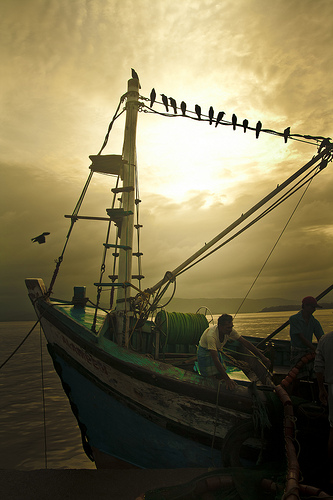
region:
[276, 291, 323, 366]
Man wearing red hat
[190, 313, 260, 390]
Man wearing white shirt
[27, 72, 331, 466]
Large dirty boat in ocean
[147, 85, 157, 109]
Bird sitting on rope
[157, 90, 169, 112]
Bird sitting on rope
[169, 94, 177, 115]
Bird sitting on rope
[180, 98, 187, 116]
Bird sitting on rope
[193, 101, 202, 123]
Bird sitting on rope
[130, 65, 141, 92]
Bird sitting on top of wooden post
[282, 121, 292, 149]
Bird sitting on rope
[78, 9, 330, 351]
Sunset over a fishing boat.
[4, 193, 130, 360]
Bird landing on the deck of a boat.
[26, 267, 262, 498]
An old boat in need of a paint job.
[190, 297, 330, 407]
Fisherman working on a boat.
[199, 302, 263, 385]
A man in a white shirt.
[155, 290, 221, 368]
Green rope on a spool.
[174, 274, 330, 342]
The cost line of a boats home port.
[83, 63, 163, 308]
the mast of a boat.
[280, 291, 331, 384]
A man looking out to see.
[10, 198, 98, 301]
A bird flying through the sky.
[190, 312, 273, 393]
man in white t shirt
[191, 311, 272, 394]
man with dark hair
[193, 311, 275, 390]
man with something green wrapped around his waist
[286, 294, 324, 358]
man in red hat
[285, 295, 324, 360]
man in blue shirt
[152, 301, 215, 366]
spool of rope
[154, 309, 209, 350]
green rope on the spool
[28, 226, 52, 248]
bird flying in the air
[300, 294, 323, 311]
mans red cap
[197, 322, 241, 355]
mans white shirt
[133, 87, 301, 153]
black birds on power line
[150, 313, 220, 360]
green spooled rope on boat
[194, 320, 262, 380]
man wearing white shirt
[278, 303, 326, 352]
man wearing blue shirt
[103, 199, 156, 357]
tall wooden pole on boat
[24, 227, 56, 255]
black bird flying in sky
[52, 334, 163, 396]
letters on side of boat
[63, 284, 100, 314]
rope tied at front of boat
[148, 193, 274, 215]
sun in clouds in sky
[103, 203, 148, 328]
rope ladder on boat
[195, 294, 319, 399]
two men on the boat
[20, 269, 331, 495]
the boat on the water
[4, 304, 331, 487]
the large body of water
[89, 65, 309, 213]
the sun shining in the sky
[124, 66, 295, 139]
bird perched on a rope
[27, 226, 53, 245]
a bird flying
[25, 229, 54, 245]
a bird in the sky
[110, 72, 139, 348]
white pole on the boat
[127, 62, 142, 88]
bird at the top of the white pole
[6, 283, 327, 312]
mountains in the distance